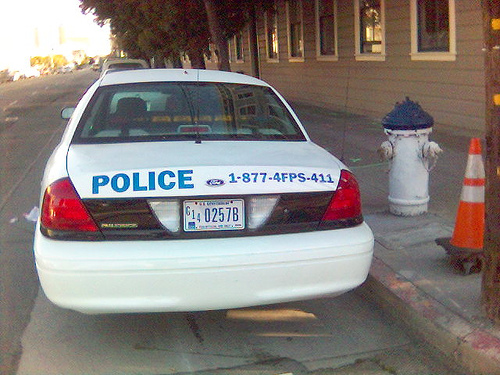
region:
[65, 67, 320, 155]
window of a car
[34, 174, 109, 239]
light of a car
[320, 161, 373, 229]
light of a car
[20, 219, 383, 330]
bumper of a car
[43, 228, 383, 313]
white bumper of a car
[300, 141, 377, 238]
tail light of a car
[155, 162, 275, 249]
plate of a car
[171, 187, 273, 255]
license plate of a car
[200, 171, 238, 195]
brand of a car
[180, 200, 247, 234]
license plate on car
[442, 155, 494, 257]
orange safety cone on sidewalk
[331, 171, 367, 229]
right brake light on car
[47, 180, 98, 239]
left brake light on car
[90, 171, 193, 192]
police written in blue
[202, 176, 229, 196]
ford logo on back of car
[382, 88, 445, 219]
white and blue hydrant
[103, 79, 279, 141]
back window on car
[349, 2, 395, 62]
window on side of house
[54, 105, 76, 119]
side view mirror on car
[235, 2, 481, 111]
row of windows on building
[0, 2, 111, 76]
light in daytime sky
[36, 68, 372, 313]
back of parked police car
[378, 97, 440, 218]
blue and white fire hydrant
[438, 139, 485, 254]
orange and white cone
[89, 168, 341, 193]
blue letters and numbers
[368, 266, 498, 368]
worn red curb paint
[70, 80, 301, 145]
back window of police car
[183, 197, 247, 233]
license plate on vehicle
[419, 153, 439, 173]
chain hanging from hydrant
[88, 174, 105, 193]
letter p on car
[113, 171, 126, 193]
letter o on car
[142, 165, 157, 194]
letter i on car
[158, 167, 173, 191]
letter c on car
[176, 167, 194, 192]
letter e on car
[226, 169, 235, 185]
number 1 on car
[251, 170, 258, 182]
number 7 on car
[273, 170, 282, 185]
number 4 on car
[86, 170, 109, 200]
The letter is blue.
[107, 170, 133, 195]
The letter is blue.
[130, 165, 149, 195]
The letter is blue.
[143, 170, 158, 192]
The letter is blue.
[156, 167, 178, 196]
The letter is blue.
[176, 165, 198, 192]
The letter is blue.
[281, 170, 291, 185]
The letter is blue.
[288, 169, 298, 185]
The letter is blue.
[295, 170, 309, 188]
The letter is blue.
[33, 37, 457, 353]
The police car is parked near a fire hydrant.